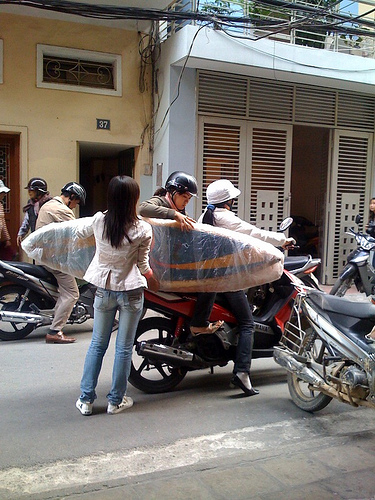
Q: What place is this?
A: It is a street.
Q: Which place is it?
A: It is a street.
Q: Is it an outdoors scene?
A: Yes, it is outdoors.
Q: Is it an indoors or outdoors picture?
A: It is outdoors.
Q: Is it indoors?
A: No, it is outdoors.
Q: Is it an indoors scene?
A: No, it is outdoors.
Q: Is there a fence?
A: No, there are no fences.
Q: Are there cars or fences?
A: No, there are no fences or cars.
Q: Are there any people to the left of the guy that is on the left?
A: Yes, there is a person to the left of the guy.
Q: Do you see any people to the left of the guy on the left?
A: Yes, there is a person to the left of the guy.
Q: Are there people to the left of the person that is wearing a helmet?
A: Yes, there is a person to the left of the guy.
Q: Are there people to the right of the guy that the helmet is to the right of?
A: No, the person is to the left of the guy.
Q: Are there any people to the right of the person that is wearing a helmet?
A: No, the person is to the left of the guy.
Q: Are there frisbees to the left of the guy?
A: No, there is a person to the left of the guy.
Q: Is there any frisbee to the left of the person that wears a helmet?
A: No, there is a person to the left of the guy.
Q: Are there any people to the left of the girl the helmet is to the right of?
A: Yes, there is a person to the left of the girl.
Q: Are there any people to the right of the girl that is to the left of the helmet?
A: No, the person is to the left of the girl.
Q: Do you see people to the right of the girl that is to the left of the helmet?
A: No, the person is to the left of the girl.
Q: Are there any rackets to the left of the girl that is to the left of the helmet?
A: No, there is a person to the left of the girl.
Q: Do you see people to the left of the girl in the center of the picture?
A: Yes, there is a person to the left of the girl.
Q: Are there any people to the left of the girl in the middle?
A: Yes, there is a person to the left of the girl.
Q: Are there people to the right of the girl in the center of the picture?
A: No, the person is to the left of the girl.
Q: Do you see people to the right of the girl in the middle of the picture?
A: No, the person is to the left of the girl.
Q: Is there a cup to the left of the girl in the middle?
A: No, there is a person to the left of the girl.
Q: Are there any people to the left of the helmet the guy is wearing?
A: Yes, there is a person to the left of the helmet.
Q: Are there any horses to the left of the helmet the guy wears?
A: No, there is a person to the left of the helmet.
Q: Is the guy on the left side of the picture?
A: Yes, the guy is on the left of the image.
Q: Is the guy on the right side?
A: No, the guy is on the left of the image.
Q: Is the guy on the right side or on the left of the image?
A: The guy is on the left of the image.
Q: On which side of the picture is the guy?
A: The guy is on the left of the image.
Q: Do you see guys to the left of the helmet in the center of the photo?
A: Yes, there is a guy to the left of the helmet.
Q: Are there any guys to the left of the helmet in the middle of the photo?
A: Yes, there is a guy to the left of the helmet.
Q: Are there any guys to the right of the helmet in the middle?
A: No, the guy is to the left of the helmet.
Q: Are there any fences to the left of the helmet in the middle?
A: No, there is a guy to the left of the helmet.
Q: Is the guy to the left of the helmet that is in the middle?
A: Yes, the guy is to the left of the helmet.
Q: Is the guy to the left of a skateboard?
A: No, the guy is to the left of the helmet.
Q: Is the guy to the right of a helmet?
A: No, the guy is to the left of a helmet.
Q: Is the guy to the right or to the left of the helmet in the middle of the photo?
A: The guy is to the left of the helmet.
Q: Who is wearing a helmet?
A: The guy is wearing a helmet.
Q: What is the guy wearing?
A: The guy is wearing a helmet.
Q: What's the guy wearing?
A: The guy is wearing a helmet.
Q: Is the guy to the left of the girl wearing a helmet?
A: Yes, the guy is wearing a helmet.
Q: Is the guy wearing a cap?
A: No, the guy is wearing a helmet.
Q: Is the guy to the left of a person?
A: No, the guy is to the right of a person.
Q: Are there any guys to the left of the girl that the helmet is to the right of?
A: Yes, there is a guy to the left of the girl.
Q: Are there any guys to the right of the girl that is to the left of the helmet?
A: No, the guy is to the left of the girl.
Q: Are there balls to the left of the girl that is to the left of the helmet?
A: No, there is a guy to the left of the girl.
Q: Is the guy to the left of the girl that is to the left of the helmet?
A: Yes, the guy is to the left of the girl.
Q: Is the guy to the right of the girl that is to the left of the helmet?
A: No, the guy is to the left of the girl.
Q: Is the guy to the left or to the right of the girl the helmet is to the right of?
A: The guy is to the left of the girl.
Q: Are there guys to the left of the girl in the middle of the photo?
A: Yes, there is a guy to the left of the girl.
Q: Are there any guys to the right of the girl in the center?
A: No, the guy is to the left of the girl.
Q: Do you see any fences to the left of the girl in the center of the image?
A: No, there is a guy to the left of the girl.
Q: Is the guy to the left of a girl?
A: Yes, the guy is to the left of a girl.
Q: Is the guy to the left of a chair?
A: No, the guy is to the left of a girl.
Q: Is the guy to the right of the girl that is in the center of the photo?
A: No, the guy is to the left of the girl.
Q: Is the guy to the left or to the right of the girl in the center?
A: The guy is to the left of the girl.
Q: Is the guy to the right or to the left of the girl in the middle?
A: The guy is to the left of the girl.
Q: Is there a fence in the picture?
A: No, there are no fences.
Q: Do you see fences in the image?
A: No, there are no fences.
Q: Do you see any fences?
A: No, there are no fences.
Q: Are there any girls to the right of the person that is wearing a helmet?
A: Yes, there is a girl to the right of the guy.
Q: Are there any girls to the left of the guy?
A: No, the girl is to the right of the guy.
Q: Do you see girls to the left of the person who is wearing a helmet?
A: No, the girl is to the right of the guy.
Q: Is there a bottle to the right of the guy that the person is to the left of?
A: No, there is a girl to the right of the guy.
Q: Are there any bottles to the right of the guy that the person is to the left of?
A: No, there is a girl to the right of the guy.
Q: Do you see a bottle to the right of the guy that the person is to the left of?
A: No, there is a girl to the right of the guy.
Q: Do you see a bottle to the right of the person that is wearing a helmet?
A: No, there is a girl to the right of the guy.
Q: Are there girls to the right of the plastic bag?
A: Yes, there is a girl to the right of the bag.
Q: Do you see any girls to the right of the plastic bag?
A: Yes, there is a girl to the right of the bag.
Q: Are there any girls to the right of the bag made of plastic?
A: Yes, there is a girl to the right of the bag.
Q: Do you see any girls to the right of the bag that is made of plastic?
A: Yes, there is a girl to the right of the bag.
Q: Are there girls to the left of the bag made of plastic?
A: No, the girl is to the right of the bag.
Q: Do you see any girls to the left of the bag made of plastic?
A: No, the girl is to the right of the bag.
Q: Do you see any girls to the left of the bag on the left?
A: No, the girl is to the right of the bag.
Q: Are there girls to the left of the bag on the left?
A: No, the girl is to the right of the bag.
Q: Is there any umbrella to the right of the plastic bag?
A: No, there is a girl to the right of the bag.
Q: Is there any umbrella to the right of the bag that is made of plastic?
A: No, there is a girl to the right of the bag.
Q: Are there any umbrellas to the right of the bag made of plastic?
A: No, there is a girl to the right of the bag.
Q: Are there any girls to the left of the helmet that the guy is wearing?
A: No, the girl is to the right of the helmet.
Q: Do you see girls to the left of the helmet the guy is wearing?
A: No, the girl is to the right of the helmet.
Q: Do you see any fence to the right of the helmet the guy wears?
A: No, there is a girl to the right of the helmet.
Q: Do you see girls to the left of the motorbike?
A: Yes, there is a girl to the left of the motorbike.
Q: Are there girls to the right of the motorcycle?
A: No, the girl is to the left of the motorcycle.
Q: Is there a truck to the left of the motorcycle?
A: No, there is a girl to the left of the motorcycle.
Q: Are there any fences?
A: No, there are no fences.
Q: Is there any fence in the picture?
A: No, there are no fences.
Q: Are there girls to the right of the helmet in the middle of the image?
A: Yes, there is a girl to the right of the helmet.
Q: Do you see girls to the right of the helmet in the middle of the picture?
A: Yes, there is a girl to the right of the helmet.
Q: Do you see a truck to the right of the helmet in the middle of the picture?
A: No, there is a girl to the right of the helmet.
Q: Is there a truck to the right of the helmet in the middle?
A: No, there is a girl to the right of the helmet.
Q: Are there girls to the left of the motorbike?
A: Yes, there is a girl to the left of the motorbike.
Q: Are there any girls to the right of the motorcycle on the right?
A: No, the girl is to the left of the motorcycle.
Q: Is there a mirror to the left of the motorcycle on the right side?
A: No, there is a girl to the left of the motorbike.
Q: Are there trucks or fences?
A: No, there are no fences or trucks.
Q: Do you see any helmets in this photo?
A: Yes, there is a helmet.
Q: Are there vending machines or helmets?
A: Yes, there is a helmet.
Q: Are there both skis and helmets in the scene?
A: No, there is a helmet but no skis.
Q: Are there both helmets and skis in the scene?
A: No, there is a helmet but no skis.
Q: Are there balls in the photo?
A: No, there are no balls.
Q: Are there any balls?
A: No, there are no balls.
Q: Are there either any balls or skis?
A: No, there are no balls or skis.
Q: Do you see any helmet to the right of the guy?
A: Yes, there is a helmet to the right of the guy.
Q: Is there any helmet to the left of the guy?
A: No, the helmet is to the right of the guy.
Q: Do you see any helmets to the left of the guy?
A: No, the helmet is to the right of the guy.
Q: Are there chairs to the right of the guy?
A: No, there is a helmet to the right of the guy.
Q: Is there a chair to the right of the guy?
A: No, there is a helmet to the right of the guy.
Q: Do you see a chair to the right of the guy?
A: No, there is a helmet to the right of the guy.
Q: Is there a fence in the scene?
A: No, there are no fences.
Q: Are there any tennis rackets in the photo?
A: No, there are no tennis rackets.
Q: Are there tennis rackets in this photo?
A: No, there are no tennis rackets.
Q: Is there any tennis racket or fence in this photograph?
A: No, there are no rackets or fences.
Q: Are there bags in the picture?
A: Yes, there is a bag.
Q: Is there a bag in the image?
A: Yes, there is a bag.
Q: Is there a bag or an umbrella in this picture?
A: Yes, there is a bag.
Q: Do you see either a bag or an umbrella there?
A: Yes, there is a bag.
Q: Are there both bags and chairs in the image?
A: No, there is a bag but no chairs.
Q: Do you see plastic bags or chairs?
A: Yes, there is a plastic bag.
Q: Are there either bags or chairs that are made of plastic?
A: Yes, the bag is made of plastic.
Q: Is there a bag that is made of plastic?
A: Yes, there is a bag that is made of plastic.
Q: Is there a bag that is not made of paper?
A: Yes, there is a bag that is made of plastic.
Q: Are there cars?
A: No, there are no cars.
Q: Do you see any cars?
A: No, there are no cars.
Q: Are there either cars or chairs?
A: No, there are no cars or chairs.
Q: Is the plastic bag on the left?
A: Yes, the bag is on the left of the image.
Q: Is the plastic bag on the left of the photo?
A: Yes, the bag is on the left of the image.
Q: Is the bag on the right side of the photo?
A: No, the bag is on the left of the image.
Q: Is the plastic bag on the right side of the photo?
A: No, the bag is on the left of the image.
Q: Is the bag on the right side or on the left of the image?
A: The bag is on the left of the image.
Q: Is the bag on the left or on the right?
A: The bag is on the left of the image.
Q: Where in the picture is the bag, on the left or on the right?
A: The bag is on the left of the image.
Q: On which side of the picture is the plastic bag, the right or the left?
A: The bag is on the left of the image.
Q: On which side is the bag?
A: The bag is on the left of the image.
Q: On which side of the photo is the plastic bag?
A: The bag is on the left of the image.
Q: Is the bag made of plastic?
A: Yes, the bag is made of plastic.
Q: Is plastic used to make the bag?
A: Yes, the bag is made of plastic.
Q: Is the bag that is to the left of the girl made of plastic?
A: Yes, the bag is made of plastic.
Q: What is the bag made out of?
A: The bag is made of plastic.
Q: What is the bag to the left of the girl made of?
A: The bag is made of plastic.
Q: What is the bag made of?
A: The bag is made of plastic.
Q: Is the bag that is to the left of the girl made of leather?
A: No, the bag is made of plastic.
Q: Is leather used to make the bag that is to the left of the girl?
A: No, the bag is made of plastic.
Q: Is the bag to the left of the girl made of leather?
A: No, the bag is made of plastic.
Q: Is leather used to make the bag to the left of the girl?
A: No, the bag is made of plastic.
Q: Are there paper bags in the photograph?
A: No, there is a bag but it is made of plastic.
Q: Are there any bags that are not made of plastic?
A: No, there is a bag but it is made of plastic.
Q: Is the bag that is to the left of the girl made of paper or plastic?
A: The bag is made of plastic.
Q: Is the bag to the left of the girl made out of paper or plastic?
A: The bag is made of plastic.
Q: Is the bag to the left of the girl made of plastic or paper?
A: The bag is made of plastic.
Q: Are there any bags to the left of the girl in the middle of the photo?
A: Yes, there is a bag to the left of the girl.